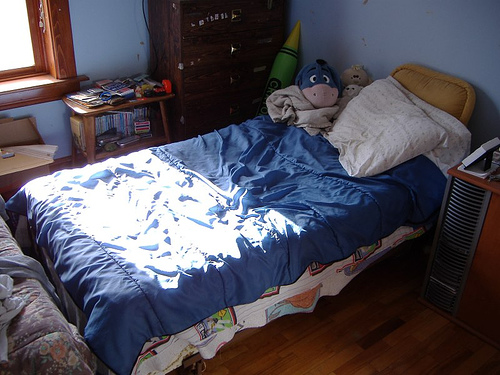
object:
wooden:
[322, 340, 340, 354]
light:
[110, 192, 252, 252]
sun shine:
[20, 147, 298, 282]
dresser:
[146, 2, 294, 143]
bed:
[6, 62, 478, 374]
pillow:
[321, 78, 451, 180]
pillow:
[382, 75, 470, 182]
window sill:
[0, 71, 64, 92]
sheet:
[133, 228, 427, 375]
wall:
[0, 2, 150, 158]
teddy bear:
[335, 64, 370, 86]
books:
[109, 110, 125, 137]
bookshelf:
[95, 133, 167, 161]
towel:
[264, 83, 341, 137]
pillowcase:
[319, 76, 450, 177]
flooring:
[189, 249, 500, 374]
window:
[0, 0, 45, 80]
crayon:
[260, 20, 302, 101]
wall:
[286, 2, 498, 132]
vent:
[421, 176, 490, 315]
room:
[0, 0, 500, 373]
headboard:
[389, 65, 477, 128]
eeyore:
[294, 56, 340, 109]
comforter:
[3, 109, 447, 374]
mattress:
[26, 113, 428, 299]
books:
[94, 117, 100, 138]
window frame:
[0, 0, 91, 110]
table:
[63, 84, 175, 165]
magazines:
[93, 76, 137, 97]